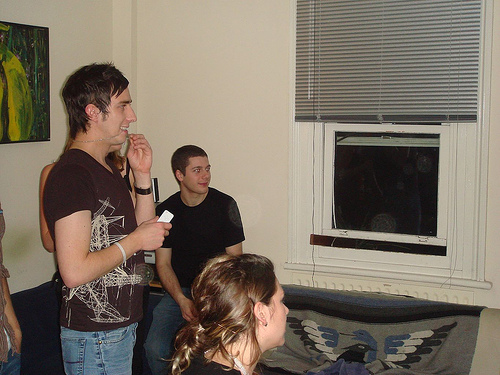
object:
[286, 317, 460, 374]
bird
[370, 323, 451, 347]
blanket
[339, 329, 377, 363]
snake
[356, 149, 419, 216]
dark night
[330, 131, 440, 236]
window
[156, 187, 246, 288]
shirt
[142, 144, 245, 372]
man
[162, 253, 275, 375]
hair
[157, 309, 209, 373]
ponytail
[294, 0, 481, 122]
blinds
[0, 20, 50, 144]
painting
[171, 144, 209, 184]
hair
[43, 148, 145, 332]
shirt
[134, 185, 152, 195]
wrist watch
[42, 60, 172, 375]
man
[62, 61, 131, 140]
hair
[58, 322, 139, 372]
jeans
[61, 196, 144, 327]
designs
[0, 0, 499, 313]
wall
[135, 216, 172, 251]
hand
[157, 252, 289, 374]
girl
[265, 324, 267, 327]
small earring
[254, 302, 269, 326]
ear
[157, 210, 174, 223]
video game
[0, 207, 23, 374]
person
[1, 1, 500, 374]
room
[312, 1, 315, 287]
cord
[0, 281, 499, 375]
bed